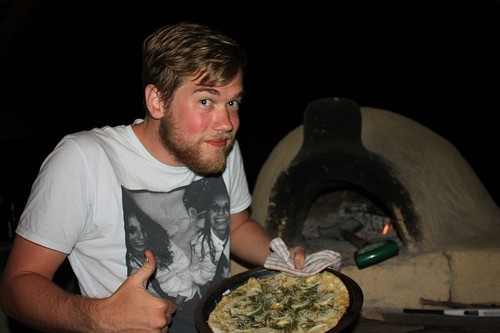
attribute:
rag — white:
[268, 235, 341, 279]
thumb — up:
[130, 246, 165, 285]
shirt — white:
[15, 122, 250, 294]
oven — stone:
[260, 89, 473, 258]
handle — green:
[351, 236, 400, 272]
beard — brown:
[156, 116, 237, 181]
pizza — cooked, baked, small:
[209, 271, 350, 329]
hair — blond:
[140, 18, 250, 89]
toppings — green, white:
[252, 292, 273, 313]